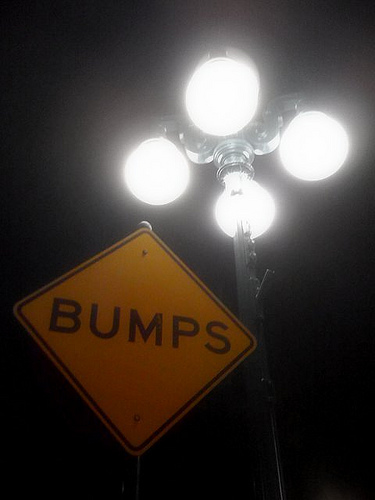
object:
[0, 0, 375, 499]
background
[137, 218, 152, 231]
top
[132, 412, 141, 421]
bolt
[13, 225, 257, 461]
sign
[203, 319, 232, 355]
s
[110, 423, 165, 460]
bottom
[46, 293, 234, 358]
word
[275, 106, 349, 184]
light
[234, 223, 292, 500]
lamp post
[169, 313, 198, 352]
letter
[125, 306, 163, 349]
letter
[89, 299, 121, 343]
letter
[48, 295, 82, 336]
letter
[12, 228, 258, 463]
boarder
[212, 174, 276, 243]
light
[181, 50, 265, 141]
light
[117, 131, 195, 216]
light